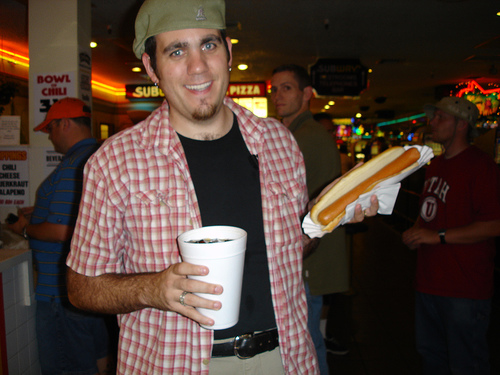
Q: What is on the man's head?
A: Hat.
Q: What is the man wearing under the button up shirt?
A: T shirt.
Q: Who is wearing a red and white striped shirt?
A: The man.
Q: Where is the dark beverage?
A: In the man's hand.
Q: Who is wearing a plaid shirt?
A: The man in the foreground.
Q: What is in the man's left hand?
A: Hot dog.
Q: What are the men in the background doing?
A: Standing in line.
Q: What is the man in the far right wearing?
A: Red t shirt.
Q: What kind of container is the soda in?
A: White cup.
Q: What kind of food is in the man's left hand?
A: Hot dog.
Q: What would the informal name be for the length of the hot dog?
A: Foot long.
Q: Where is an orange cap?
A: Head of man near support column.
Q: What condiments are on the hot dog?
A: There are none.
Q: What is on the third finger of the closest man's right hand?
A: Ring.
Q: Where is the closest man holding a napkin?
A: Left hand.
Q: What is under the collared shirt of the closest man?
A: Black t-shirt.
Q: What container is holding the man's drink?
A: Foam cup.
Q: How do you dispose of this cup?
A: Throw away.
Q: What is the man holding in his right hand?
A: A styrofoam cup.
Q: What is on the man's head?
A: A hat.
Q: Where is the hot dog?
A: In the man's left hand.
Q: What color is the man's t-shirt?
A: Black.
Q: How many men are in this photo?
A: Four.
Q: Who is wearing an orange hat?
A: The person behind the center man.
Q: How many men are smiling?
A: One.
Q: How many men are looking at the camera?
A: Two.